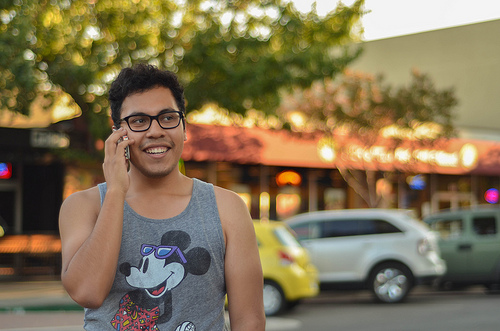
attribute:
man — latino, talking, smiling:
[58, 60, 266, 330]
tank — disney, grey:
[83, 177, 227, 331]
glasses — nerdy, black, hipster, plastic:
[121, 110, 185, 133]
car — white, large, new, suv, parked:
[278, 205, 446, 305]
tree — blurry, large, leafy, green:
[0, 2, 367, 191]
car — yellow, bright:
[221, 218, 320, 318]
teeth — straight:
[142, 147, 169, 155]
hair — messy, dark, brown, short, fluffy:
[108, 65, 187, 129]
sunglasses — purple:
[139, 241, 190, 265]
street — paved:
[0, 284, 499, 330]